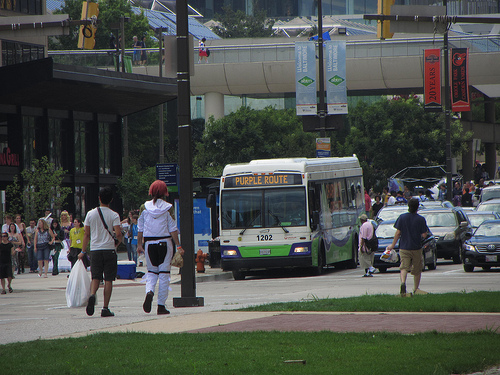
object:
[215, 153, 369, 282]
bus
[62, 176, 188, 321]
couple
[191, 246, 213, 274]
hydrant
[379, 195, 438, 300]
man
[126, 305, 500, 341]
sidewalk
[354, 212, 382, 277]
person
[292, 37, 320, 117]
banner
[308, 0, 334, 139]
pole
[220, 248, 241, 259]
light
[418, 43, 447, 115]
banner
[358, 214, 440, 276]
cars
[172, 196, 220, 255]
bus stand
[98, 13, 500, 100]
bridge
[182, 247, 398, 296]
street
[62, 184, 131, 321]
man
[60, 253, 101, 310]
bag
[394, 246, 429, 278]
shorts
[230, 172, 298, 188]
sign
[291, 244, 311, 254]
headlights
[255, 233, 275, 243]
number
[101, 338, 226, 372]
grass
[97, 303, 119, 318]
shoes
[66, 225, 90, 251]
shirt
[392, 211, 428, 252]
shirt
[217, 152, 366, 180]
bus roof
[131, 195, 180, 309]
clothes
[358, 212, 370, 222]
hat